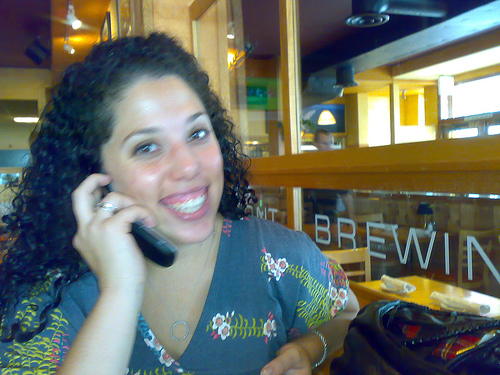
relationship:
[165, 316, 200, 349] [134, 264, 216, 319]
charm attached to necklace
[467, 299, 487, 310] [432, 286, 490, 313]
utensils inside of napkin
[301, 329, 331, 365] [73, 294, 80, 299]
bracelet around arm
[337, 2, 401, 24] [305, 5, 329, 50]
vent on top of ceiling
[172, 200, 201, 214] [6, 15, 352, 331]
teeth of lady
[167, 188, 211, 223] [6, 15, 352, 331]
lips of lady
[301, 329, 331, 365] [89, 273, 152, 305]
bracelet around wrist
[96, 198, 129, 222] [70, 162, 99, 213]
rings on finger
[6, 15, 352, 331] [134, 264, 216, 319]
lady wearing necklace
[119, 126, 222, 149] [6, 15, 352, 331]
eyes of lady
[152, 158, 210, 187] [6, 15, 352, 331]
nose of lady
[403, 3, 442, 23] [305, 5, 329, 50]
fan on top of ceiling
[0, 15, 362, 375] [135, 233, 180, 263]
lady talking on cell phone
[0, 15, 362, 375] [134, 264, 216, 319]
lady wearing necklace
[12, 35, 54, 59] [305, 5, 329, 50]
speaker on ceiling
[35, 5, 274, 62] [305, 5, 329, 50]
lights on ceiling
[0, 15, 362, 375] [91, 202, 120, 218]
lady wearing ring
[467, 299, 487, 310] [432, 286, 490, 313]
utensils inside napkin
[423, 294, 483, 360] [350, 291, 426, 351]
bag on top of table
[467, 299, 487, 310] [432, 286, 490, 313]
utensils in napkin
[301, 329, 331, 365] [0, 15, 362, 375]
bracelet on lady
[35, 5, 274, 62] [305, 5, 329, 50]
lights hanging from ceiling